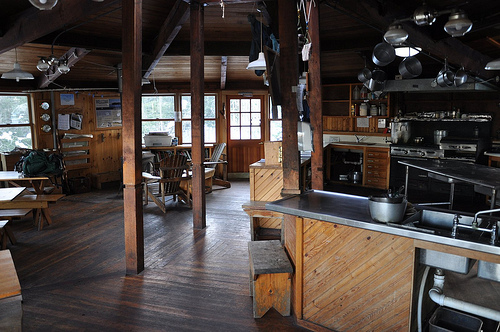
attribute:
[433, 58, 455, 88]
pot — silver, hanging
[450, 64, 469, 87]
pot — silver, hanging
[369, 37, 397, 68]
pot — silver, hanging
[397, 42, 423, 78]
pot — silver, hanging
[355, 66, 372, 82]
pot — silver, hanging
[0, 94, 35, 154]
window — sash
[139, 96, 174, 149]
window — sash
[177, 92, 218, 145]
window — sash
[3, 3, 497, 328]
restaurant — wood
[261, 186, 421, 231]
countertop — stainless steel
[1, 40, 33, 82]
lamp shade — hanging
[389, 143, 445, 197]
oven — silver, black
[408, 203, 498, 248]
sink — stainless steel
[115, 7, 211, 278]
posts — wooden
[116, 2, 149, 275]
post — wooden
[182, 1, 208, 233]
post — wooden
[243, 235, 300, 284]
bench — small, wooden, gray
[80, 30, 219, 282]
beam — tall, brown, wooden, reaching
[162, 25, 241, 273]
beam — reaching, tall, brown, wooden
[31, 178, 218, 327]
flooring — dark brown, hardwood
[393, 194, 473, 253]
sink — silver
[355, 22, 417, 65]
pots — silver, hanging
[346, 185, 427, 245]
pots — stacked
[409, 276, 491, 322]
tube — white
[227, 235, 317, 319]
bench — wooden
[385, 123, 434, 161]
pot — large, silver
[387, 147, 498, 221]
table — silver, retangular